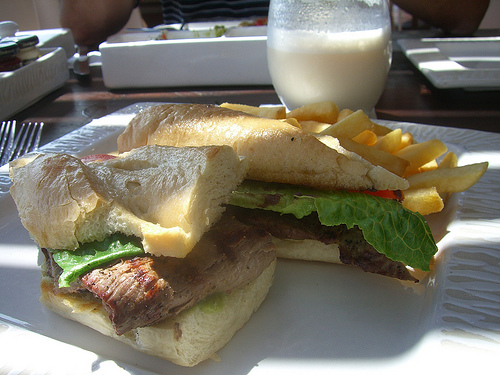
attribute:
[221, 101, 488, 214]
french fries — tan , white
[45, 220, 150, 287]
lettuce — green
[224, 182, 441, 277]
lettuce — green 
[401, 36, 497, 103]
an empty — white, plate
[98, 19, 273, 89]
tray — empty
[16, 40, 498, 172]
table — brown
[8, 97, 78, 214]
forks — silver 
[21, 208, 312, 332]
meat — piece, fried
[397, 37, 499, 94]
tray — empty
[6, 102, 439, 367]
sandwich — two halves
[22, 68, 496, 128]
person — sitting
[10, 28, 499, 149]
table — brown, wooden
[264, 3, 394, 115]
glass — clear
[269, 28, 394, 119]
drink — white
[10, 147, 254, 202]
roll — white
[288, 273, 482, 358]
plate — white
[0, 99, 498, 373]
plate — white 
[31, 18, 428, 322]
table — wooden